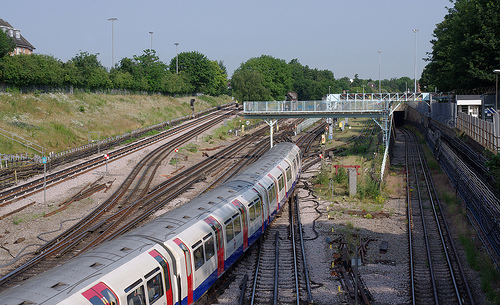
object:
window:
[189, 244, 204, 272]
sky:
[0, 0, 452, 80]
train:
[0, 104, 475, 305]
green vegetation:
[321, 163, 379, 198]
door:
[203, 216, 225, 277]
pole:
[174, 43, 179, 74]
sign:
[42, 157, 47, 163]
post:
[40, 157, 51, 203]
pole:
[348, 168, 358, 198]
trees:
[42, 52, 173, 88]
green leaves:
[56, 52, 106, 87]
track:
[236, 191, 309, 305]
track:
[293, 121, 328, 157]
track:
[0, 105, 301, 291]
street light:
[108, 18, 117, 20]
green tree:
[441, 0, 500, 67]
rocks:
[302, 226, 410, 303]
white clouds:
[265, 14, 329, 41]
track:
[402, 131, 469, 303]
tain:
[0, 141, 299, 305]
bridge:
[244, 99, 393, 147]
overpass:
[244, 100, 391, 119]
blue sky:
[2, 0, 454, 80]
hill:
[2, 83, 238, 194]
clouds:
[0, 0, 426, 59]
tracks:
[234, 111, 477, 305]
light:
[174, 43, 180, 47]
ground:
[1, 89, 499, 303]